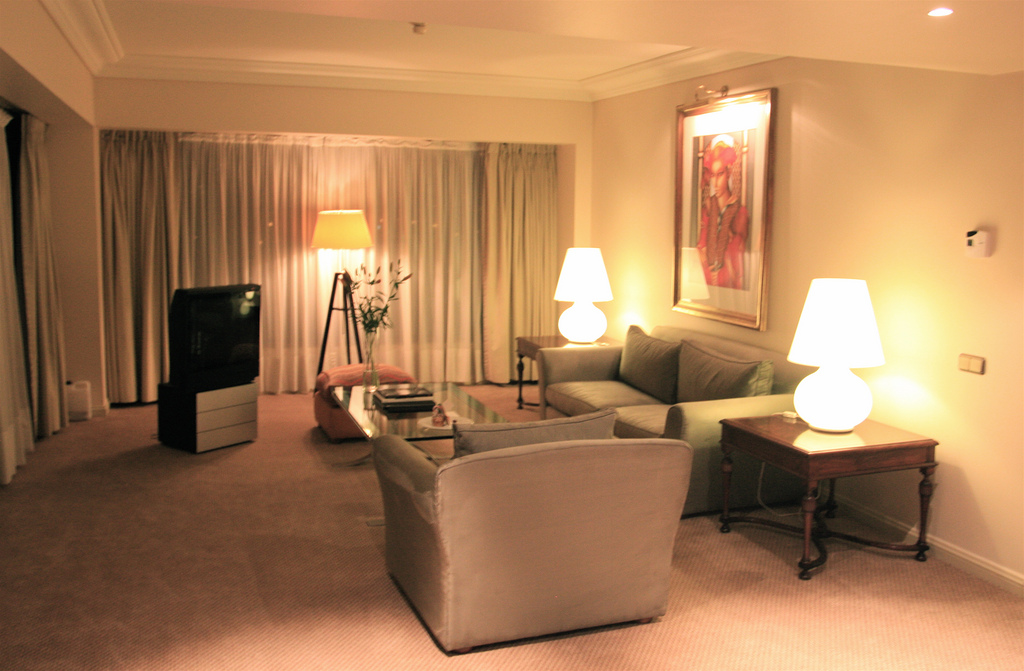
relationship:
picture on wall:
[662, 101, 780, 346] [805, 99, 936, 245]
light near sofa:
[542, 235, 658, 395] [574, 319, 747, 440]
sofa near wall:
[574, 319, 747, 440] [805, 99, 936, 245]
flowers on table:
[347, 288, 411, 374] [348, 380, 485, 457]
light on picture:
[542, 235, 658, 395] [662, 101, 780, 346]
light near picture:
[542, 235, 658, 395] [662, 101, 780, 346]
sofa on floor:
[574, 319, 747, 440] [91, 486, 384, 638]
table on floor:
[348, 380, 485, 457] [91, 486, 384, 638]